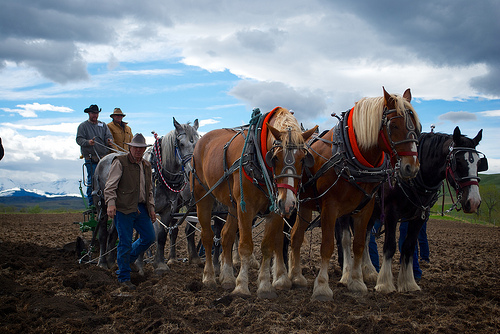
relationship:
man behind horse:
[79, 106, 116, 212] [150, 116, 200, 274]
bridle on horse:
[246, 111, 311, 218] [189, 108, 315, 298]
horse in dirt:
[298, 90, 417, 295] [1, 213, 500, 329]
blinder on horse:
[448, 157, 487, 169] [375, 126, 487, 291]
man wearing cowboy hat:
[108, 136, 160, 289] [126, 134, 151, 149]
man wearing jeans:
[108, 136, 160, 289] [112, 201, 158, 286]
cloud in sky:
[2, 2, 499, 117] [2, 55, 499, 172]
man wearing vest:
[108, 136, 160, 289] [113, 153, 152, 215]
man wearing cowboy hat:
[108, 106, 135, 151] [109, 107, 124, 117]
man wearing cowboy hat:
[79, 106, 116, 212] [83, 102, 101, 113]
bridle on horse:
[153, 135, 183, 194] [150, 116, 200, 274]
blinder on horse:
[265, 150, 317, 171] [189, 108, 315, 298]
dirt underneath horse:
[1, 213, 500, 329] [189, 108, 315, 298]